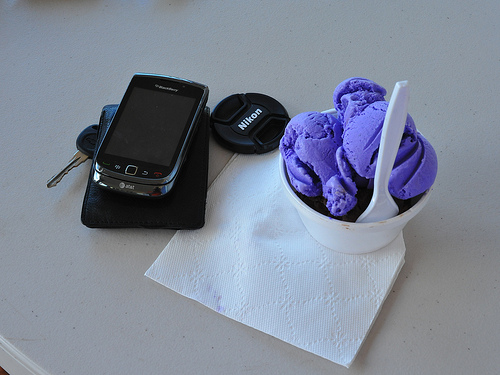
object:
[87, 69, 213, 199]
cellphone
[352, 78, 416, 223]
spoon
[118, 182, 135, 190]
logo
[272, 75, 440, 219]
ice cream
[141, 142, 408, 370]
bad napkin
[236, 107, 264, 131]
brand name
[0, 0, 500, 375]
surfboard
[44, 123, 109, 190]
black key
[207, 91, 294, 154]
camera lens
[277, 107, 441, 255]
bowl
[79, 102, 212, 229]
wallet